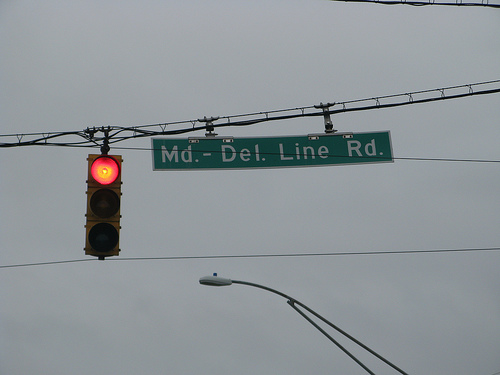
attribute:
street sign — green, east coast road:
[150, 128, 394, 172]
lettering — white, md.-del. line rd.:
[160, 136, 383, 164]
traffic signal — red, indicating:
[82, 153, 124, 260]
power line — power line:
[0, 246, 499, 269]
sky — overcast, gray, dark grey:
[1, 0, 499, 375]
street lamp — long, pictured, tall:
[198, 272, 408, 374]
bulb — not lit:
[90, 188, 120, 217]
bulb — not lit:
[87, 223, 119, 251]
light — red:
[91, 157, 119, 186]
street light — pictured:
[198, 262, 406, 372]